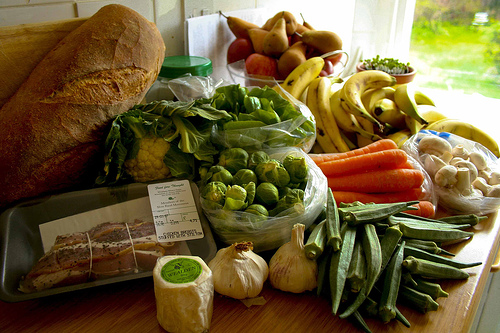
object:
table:
[0, 105, 500, 333]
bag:
[401, 130, 500, 215]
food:
[2, 3, 500, 332]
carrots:
[319, 148, 407, 177]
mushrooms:
[416, 135, 452, 155]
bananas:
[337, 69, 393, 134]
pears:
[262, 11, 289, 55]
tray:
[0, 178, 218, 303]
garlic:
[209, 241, 270, 301]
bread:
[0, 2, 162, 204]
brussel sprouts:
[218, 147, 248, 174]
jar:
[160, 55, 213, 79]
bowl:
[226, 59, 346, 90]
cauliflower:
[128, 138, 168, 182]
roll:
[17, 215, 174, 294]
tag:
[146, 180, 204, 244]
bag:
[197, 144, 327, 252]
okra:
[326, 187, 342, 250]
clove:
[284, 255, 308, 294]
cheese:
[152, 256, 215, 333]